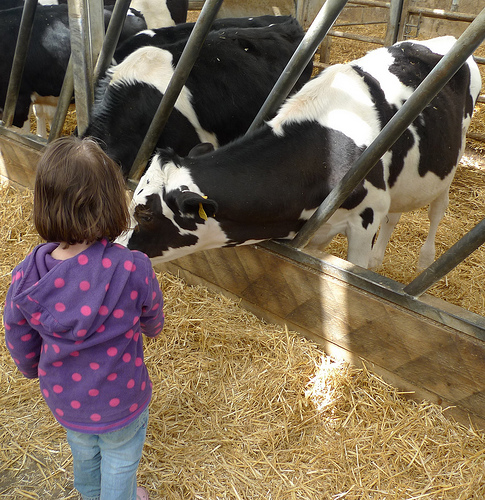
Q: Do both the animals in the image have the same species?
A: Yes, all the animals are cows.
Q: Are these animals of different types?
A: No, all the animals are cows.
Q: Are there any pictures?
A: No, there are no pictures.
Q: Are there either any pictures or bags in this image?
A: No, there are no pictures or bags.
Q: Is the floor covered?
A: Yes, the floor is covered.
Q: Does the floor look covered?
A: Yes, the floor is covered.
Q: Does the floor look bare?
A: No, the floor is covered.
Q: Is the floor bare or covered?
A: The floor is covered.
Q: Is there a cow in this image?
A: Yes, there is a cow.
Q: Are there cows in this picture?
A: Yes, there is a cow.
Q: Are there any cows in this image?
A: Yes, there is a cow.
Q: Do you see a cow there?
A: Yes, there is a cow.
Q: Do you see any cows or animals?
A: Yes, there is a cow.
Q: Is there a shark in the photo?
A: No, there are no sharks.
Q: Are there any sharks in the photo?
A: No, there are no sharks.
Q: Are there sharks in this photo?
A: No, there are no sharks.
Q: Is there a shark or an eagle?
A: No, there are no sharks or eagles.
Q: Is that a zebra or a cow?
A: That is a cow.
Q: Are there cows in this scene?
A: Yes, there is a cow.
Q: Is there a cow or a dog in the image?
A: Yes, there is a cow.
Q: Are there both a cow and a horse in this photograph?
A: No, there is a cow but no horses.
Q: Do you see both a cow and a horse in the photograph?
A: No, there is a cow but no horses.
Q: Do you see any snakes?
A: No, there are no snakes.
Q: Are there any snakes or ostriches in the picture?
A: No, there are no snakes or ostriches.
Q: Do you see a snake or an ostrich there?
A: No, there are no snakes or ostriches.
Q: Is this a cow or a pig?
A: This is a cow.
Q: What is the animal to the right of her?
A: The animal is a cow.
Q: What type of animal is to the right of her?
A: The animal is a cow.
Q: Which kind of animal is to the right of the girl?
A: The animal is a cow.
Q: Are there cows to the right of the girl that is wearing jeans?
A: Yes, there is a cow to the right of the girl.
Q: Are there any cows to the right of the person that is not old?
A: Yes, there is a cow to the right of the girl.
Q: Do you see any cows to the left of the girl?
A: No, the cow is to the right of the girl.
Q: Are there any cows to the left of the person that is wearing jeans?
A: No, the cow is to the right of the girl.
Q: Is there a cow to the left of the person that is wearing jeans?
A: No, the cow is to the right of the girl.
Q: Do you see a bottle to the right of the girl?
A: No, there is a cow to the right of the girl.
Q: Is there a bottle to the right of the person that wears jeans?
A: No, there is a cow to the right of the girl.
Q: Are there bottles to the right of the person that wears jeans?
A: No, there is a cow to the right of the girl.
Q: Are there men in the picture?
A: No, there are no men.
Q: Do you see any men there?
A: No, there are no men.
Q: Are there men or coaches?
A: No, there are no men or coaches.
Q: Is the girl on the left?
A: Yes, the girl is on the left of the image.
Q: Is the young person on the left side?
A: Yes, the girl is on the left of the image.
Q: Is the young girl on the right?
A: No, the girl is on the left of the image.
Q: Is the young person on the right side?
A: No, the girl is on the left of the image.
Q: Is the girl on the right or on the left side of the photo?
A: The girl is on the left of the image.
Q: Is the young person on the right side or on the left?
A: The girl is on the left of the image.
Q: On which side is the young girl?
A: The girl is on the left of the image.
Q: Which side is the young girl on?
A: The girl is on the left of the image.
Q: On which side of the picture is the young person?
A: The girl is on the left of the image.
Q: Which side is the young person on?
A: The girl is on the left of the image.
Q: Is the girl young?
A: Yes, the girl is young.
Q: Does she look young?
A: Yes, the girl is young.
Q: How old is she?
A: The girl is young.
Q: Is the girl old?
A: No, the girl is young.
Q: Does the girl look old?
A: No, the girl is young.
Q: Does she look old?
A: No, the girl is young.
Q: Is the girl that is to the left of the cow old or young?
A: The girl is young.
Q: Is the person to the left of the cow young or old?
A: The girl is young.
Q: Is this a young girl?
A: Yes, this is a young girl.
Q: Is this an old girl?
A: No, this is a young girl.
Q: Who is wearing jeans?
A: The girl is wearing jeans.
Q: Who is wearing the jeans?
A: The girl is wearing jeans.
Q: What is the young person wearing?
A: The girl is wearing jeans.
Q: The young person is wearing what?
A: The girl is wearing jeans.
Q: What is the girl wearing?
A: The girl is wearing jeans.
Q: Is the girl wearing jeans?
A: Yes, the girl is wearing jeans.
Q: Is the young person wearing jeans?
A: Yes, the girl is wearing jeans.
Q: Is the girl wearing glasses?
A: No, the girl is wearing jeans.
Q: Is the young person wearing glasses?
A: No, the girl is wearing jeans.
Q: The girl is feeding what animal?
A: The girl is feeding the cow.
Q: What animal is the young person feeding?
A: The girl is feeding the cow.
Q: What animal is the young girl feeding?
A: The girl is feeding the cow.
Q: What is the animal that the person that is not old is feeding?
A: The animal is a cow.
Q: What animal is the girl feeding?
A: The girl is feeding the cow.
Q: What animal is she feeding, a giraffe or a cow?
A: The girl is feeding a cow.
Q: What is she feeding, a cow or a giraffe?
A: The girl is feeding a cow.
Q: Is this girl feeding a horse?
A: No, the girl is feeding the cow.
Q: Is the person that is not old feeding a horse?
A: No, the girl is feeding the cow.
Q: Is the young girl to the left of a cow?
A: Yes, the girl is to the left of a cow.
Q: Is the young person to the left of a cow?
A: Yes, the girl is to the left of a cow.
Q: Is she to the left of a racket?
A: No, the girl is to the left of a cow.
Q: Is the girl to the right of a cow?
A: No, the girl is to the left of a cow.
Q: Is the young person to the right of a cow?
A: No, the girl is to the left of a cow.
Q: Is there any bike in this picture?
A: No, there are no bikes.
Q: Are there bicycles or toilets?
A: No, there are no bicycles or toilets.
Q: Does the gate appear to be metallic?
A: Yes, the gate is metallic.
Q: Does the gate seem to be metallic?
A: Yes, the gate is metallic.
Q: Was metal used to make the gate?
A: Yes, the gate is made of metal.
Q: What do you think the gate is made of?
A: The gate is made of metal.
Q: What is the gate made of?
A: The gate is made of metal.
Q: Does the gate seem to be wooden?
A: No, the gate is metallic.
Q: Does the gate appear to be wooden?
A: No, the gate is metallic.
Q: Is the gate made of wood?
A: No, the gate is made of metal.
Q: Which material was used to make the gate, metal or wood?
A: The gate is made of metal.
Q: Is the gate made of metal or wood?
A: The gate is made of metal.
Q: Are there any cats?
A: No, there are no cats.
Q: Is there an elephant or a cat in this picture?
A: No, there are no cats or elephants.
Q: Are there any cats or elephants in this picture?
A: No, there are no cats or elephants.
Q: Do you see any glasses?
A: No, there are no glasses.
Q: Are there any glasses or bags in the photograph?
A: No, there are no glasses or bags.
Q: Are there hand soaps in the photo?
A: No, there are no hand soaps.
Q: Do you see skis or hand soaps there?
A: No, there are no hand soaps or skis.